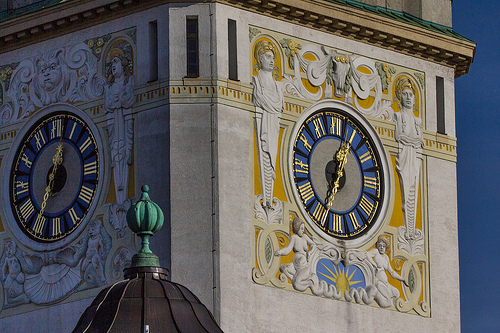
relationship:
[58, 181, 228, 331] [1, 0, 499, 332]
part of tower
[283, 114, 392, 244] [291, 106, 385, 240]
face to clock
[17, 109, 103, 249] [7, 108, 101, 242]
face to clock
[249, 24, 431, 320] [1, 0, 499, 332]
portrait in tower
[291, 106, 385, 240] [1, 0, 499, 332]
clock on tower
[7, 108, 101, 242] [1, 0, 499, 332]
clock on tower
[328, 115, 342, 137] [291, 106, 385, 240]
number on clock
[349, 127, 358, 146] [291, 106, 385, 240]
number on clock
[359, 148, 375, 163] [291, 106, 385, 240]
number on clock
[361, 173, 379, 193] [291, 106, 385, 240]
number on clock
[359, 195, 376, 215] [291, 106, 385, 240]
number on clock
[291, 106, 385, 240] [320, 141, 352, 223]
clock with hands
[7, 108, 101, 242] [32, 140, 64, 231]
clock with hands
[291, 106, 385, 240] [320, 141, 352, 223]
clock has hands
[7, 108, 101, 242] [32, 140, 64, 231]
clock has hands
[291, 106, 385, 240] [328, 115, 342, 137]
clock has number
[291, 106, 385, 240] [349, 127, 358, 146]
clock has number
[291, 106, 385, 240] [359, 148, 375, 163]
clock has number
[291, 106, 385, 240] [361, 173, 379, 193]
clock has number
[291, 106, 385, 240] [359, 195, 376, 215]
clock has number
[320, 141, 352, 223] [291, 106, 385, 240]
hands on clock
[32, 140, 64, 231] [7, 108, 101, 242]
hands on clock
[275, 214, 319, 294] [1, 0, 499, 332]
statue on tower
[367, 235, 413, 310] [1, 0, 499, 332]
statue on tower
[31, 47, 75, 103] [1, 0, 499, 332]
lion face on tower